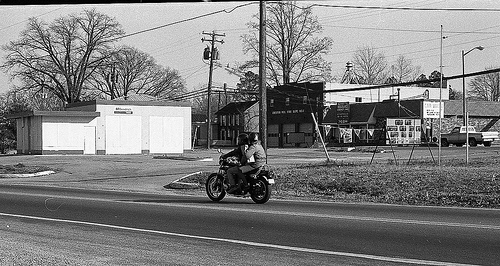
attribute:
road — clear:
[0, 181, 480, 263]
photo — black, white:
[1, 1, 484, 262]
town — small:
[1, 59, 484, 159]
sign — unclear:
[385, 115, 423, 146]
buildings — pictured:
[203, 72, 492, 153]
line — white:
[8, 201, 398, 263]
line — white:
[10, 206, 419, 264]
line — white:
[13, 210, 454, 264]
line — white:
[13, 183, 499, 234]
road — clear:
[23, 184, 496, 264]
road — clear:
[48, 145, 464, 193]